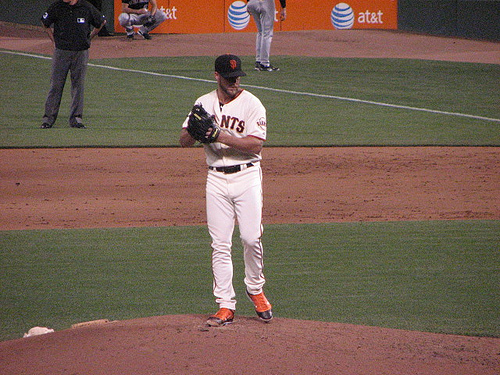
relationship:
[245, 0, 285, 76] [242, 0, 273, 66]
player in pants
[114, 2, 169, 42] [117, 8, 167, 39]
player in pants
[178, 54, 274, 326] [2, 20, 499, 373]
pitcher on field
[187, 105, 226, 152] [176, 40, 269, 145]
glove of pitcher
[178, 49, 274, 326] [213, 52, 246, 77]
pitcher wearing hat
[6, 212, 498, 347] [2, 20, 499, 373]
grass on field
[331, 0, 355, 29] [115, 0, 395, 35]
logo on advertisement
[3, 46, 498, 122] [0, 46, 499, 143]
line painted on grass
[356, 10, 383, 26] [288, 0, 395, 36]
at&t on wall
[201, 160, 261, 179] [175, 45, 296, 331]
belt around player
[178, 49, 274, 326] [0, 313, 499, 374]
pitcher standing on mound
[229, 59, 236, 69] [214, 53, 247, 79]
logo on cap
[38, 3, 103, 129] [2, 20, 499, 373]
umpire standing on field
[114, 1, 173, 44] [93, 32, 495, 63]
player crouching in dirt